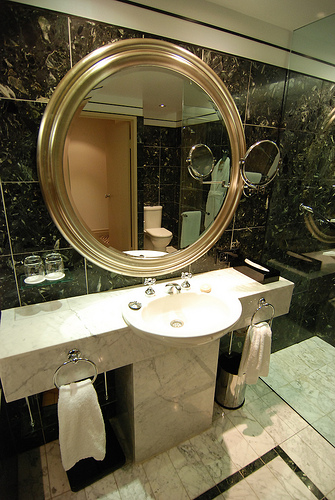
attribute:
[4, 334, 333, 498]
floor — marble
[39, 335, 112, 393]
ring — silver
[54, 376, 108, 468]
towel — white, long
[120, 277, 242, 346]
sink — large, white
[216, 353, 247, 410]
trashcan — small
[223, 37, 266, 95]
wall — marble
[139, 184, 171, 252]
toilet — white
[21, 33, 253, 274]
wall mirror — large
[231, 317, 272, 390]
towel — long, white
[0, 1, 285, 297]
wall — marble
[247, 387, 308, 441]
floor — tile